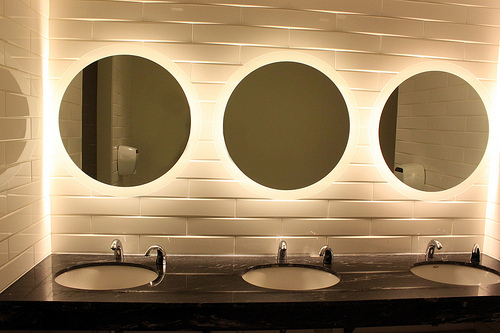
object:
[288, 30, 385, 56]
brick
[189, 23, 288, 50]
brick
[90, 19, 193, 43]
brick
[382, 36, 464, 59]
brick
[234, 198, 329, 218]
brick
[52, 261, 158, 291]
sink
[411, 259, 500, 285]
sink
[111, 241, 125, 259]
faucet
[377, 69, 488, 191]
mirror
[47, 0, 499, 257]
wall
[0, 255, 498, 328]
counter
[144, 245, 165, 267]
soap dispenser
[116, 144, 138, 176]
hand dryer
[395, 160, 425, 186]
hand dryer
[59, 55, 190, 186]
reflection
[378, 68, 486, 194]
reflection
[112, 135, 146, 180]
white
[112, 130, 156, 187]
soap dispensor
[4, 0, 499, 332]
bathroom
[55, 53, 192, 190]
mirror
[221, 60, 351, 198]
mirror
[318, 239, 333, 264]
soap dispenser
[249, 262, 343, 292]
sink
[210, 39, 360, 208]
circle mirror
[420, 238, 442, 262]
faucet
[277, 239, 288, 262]
faucet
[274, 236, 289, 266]
tap